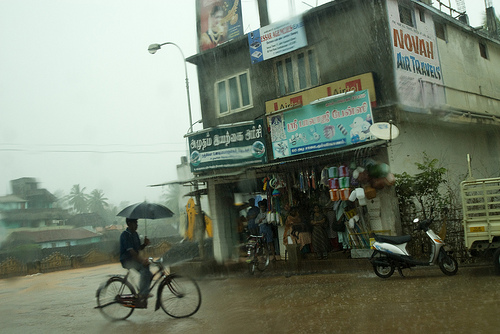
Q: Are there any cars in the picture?
A: No, there are no cars.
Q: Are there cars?
A: No, there are no cars.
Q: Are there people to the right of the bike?
A: Yes, there are people to the right of the bike.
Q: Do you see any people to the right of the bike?
A: Yes, there are people to the right of the bike.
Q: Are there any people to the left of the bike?
A: No, the people are to the right of the bike.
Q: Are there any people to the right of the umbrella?
A: Yes, there are people to the right of the umbrella.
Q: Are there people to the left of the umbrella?
A: No, the people are to the right of the umbrella.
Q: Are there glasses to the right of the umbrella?
A: No, there are people to the right of the umbrella.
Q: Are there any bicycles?
A: Yes, there is a bicycle.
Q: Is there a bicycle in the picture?
A: Yes, there is a bicycle.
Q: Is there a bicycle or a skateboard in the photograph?
A: Yes, there is a bicycle.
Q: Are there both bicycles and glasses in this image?
A: No, there is a bicycle but no glasses.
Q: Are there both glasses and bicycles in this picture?
A: No, there is a bicycle but no glasses.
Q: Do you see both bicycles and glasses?
A: No, there is a bicycle but no glasses.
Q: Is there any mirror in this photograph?
A: No, there are no mirrors.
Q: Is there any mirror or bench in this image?
A: No, there are no mirrors or benches.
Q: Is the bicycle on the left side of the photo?
A: Yes, the bicycle is on the left of the image.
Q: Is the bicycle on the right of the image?
A: No, the bicycle is on the left of the image.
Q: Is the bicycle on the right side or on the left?
A: The bicycle is on the left of the image.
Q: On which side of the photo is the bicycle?
A: The bicycle is on the left of the image.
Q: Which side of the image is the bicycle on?
A: The bicycle is on the left of the image.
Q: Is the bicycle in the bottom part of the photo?
A: Yes, the bicycle is in the bottom of the image.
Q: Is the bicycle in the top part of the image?
A: No, the bicycle is in the bottom of the image.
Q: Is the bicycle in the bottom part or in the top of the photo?
A: The bicycle is in the bottom of the image.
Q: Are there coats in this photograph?
A: No, there are no coats.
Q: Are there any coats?
A: No, there are no coats.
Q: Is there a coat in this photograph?
A: No, there are no coats.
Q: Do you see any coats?
A: No, there are no coats.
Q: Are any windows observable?
A: Yes, there is a window.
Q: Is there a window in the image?
A: Yes, there is a window.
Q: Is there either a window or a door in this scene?
A: Yes, there is a window.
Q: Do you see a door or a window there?
A: Yes, there is a window.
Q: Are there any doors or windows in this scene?
A: Yes, there is a window.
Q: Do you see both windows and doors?
A: No, there is a window but no doors.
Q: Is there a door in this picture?
A: No, there are no doors.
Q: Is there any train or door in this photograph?
A: No, there are no doors or trains.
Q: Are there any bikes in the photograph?
A: Yes, there is a bike.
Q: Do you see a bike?
A: Yes, there is a bike.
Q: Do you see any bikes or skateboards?
A: Yes, there is a bike.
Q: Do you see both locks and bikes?
A: No, there is a bike but no locks.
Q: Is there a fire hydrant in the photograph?
A: No, there are no fire hydrants.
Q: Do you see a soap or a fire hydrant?
A: No, there are no fire hydrants or soaps.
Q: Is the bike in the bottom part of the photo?
A: Yes, the bike is in the bottom of the image.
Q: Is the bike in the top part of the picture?
A: No, the bike is in the bottom of the image.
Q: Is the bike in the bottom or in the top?
A: The bike is in the bottom of the image.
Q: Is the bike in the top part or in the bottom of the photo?
A: The bike is in the bottom of the image.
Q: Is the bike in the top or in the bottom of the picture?
A: The bike is in the bottom of the image.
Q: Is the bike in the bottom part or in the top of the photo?
A: The bike is in the bottom of the image.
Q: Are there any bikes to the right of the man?
A: Yes, there is a bike to the right of the man.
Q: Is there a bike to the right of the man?
A: Yes, there is a bike to the right of the man.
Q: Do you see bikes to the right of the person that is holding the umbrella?
A: Yes, there is a bike to the right of the man.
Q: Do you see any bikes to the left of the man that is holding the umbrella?
A: No, the bike is to the right of the man.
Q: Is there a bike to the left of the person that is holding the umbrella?
A: No, the bike is to the right of the man.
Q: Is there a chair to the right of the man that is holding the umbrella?
A: No, there is a bike to the right of the man.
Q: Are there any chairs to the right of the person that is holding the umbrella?
A: No, there is a bike to the right of the man.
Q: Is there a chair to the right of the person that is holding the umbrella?
A: No, there is a bike to the right of the man.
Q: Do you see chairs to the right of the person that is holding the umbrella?
A: No, there is a bike to the right of the man.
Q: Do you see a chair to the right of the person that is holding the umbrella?
A: No, there is a bike to the right of the man.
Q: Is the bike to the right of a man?
A: Yes, the bike is to the right of a man.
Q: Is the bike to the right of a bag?
A: No, the bike is to the right of a man.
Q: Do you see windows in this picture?
A: Yes, there is a window.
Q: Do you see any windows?
A: Yes, there is a window.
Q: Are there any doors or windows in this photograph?
A: Yes, there is a window.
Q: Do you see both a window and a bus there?
A: No, there is a window but no buses.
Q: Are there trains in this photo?
A: No, there are no trains.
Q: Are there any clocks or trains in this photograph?
A: No, there are no trains or clocks.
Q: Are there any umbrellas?
A: Yes, there is an umbrella.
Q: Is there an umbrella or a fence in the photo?
A: Yes, there is an umbrella.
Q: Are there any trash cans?
A: No, there are no trash cans.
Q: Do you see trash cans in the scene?
A: No, there are no trash cans.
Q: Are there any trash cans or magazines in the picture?
A: No, there are no trash cans or magazines.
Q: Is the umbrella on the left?
A: Yes, the umbrella is on the left of the image.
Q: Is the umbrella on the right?
A: No, the umbrella is on the left of the image.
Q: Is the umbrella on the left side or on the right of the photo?
A: The umbrella is on the left of the image.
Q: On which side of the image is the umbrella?
A: The umbrella is on the left of the image.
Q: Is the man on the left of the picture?
A: Yes, the man is on the left of the image.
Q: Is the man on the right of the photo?
A: No, the man is on the left of the image.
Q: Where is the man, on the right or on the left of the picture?
A: The man is on the left of the image.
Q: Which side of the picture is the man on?
A: The man is on the left of the image.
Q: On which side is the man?
A: The man is on the left of the image.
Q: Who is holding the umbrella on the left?
A: The man is holding the umbrella.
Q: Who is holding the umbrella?
A: The man is holding the umbrella.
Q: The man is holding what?
A: The man is holding the umbrella.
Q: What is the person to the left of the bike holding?
A: The man is holding the umbrella.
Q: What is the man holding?
A: The man is holding the umbrella.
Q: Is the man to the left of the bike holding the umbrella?
A: Yes, the man is holding the umbrella.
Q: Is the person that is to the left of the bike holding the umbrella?
A: Yes, the man is holding the umbrella.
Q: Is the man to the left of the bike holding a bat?
A: No, the man is holding the umbrella.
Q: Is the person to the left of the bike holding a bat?
A: No, the man is holding the umbrella.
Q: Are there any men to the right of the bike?
A: No, the man is to the left of the bike.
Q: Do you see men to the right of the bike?
A: No, the man is to the left of the bike.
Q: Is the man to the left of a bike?
A: Yes, the man is to the left of a bike.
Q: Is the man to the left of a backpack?
A: No, the man is to the left of a bike.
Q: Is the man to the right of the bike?
A: No, the man is to the left of the bike.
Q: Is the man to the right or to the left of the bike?
A: The man is to the left of the bike.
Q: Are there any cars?
A: No, there are no cars.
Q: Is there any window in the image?
A: Yes, there is a window.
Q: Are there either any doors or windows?
A: Yes, there is a window.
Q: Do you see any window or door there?
A: Yes, there is a window.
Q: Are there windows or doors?
A: Yes, there is a window.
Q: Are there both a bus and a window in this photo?
A: No, there is a window but no buses.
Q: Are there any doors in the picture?
A: No, there are no doors.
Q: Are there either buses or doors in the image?
A: No, there are no doors or buses.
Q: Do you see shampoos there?
A: No, there are no shampoos.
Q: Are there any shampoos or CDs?
A: No, there are no shampoos or cds.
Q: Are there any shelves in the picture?
A: No, there are no shelves.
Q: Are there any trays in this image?
A: No, there are no trays.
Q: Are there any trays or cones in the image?
A: No, there are no trays or cones.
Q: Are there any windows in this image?
A: Yes, there is a window.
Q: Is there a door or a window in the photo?
A: Yes, there is a window.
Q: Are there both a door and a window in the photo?
A: No, there is a window but no doors.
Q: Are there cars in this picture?
A: No, there are no cars.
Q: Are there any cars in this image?
A: No, there are no cars.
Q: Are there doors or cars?
A: No, there are no cars or doors.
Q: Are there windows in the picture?
A: Yes, there is a window.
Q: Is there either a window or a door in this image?
A: Yes, there is a window.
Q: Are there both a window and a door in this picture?
A: No, there is a window but no doors.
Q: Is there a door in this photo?
A: No, there are no doors.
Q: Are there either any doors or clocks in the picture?
A: No, there are no doors or clocks.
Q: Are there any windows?
A: Yes, there is a window.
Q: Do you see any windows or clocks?
A: Yes, there is a window.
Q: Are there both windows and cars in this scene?
A: No, there is a window but no cars.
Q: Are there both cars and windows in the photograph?
A: No, there is a window but no cars.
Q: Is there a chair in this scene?
A: No, there are no chairs.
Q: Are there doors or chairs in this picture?
A: No, there are no chairs or doors.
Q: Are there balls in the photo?
A: No, there are no balls.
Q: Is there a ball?
A: No, there are no balls.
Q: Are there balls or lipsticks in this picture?
A: No, there are no balls or lipsticks.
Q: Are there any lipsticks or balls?
A: No, there are no balls or lipsticks.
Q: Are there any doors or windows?
A: Yes, there is a window.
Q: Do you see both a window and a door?
A: No, there is a window but no doors.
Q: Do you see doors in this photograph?
A: No, there are no doors.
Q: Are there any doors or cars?
A: No, there are no doors or cars.